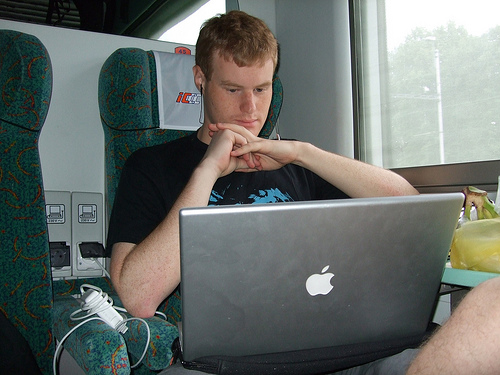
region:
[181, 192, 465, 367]
apple laptop cover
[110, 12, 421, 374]
man sitting down in seat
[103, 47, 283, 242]
velvet green seat on train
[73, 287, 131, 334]
white controller for seat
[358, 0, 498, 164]
thick window on train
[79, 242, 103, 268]
electric outlet with black cover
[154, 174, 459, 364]
the laptop is silver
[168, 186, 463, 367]
the laptop is silver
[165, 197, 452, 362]
the laptop is silver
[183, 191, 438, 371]
the laptop is silver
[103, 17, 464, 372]
the man with laptop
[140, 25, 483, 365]
the man with laptop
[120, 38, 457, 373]
the man with laptop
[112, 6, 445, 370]
the man with laptop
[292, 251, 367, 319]
this is an apple logo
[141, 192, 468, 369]
this is a laptop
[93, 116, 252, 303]
the hand of a person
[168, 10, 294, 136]
the head of a person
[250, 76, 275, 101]
the eye of a person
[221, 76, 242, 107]
the eye of a person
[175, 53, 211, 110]
the ear of a person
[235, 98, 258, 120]
the nose of a person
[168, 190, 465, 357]
silver laptop with white apple logo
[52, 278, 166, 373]
gray cord wrapped around charger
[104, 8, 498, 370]
man with a laptop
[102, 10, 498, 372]
man wearing a black shirt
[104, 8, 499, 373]
man sitting on a seat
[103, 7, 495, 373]
man with hairy leg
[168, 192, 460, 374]
laptop on a laptop case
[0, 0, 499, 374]
inside of a bus with green seats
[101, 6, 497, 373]
man with earbuds in his ears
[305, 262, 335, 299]
apple sign on back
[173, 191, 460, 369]
the grey laptop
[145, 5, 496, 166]
windows on the right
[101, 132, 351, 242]
a black and blue shirt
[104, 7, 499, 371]
a man sitting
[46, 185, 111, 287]
a port in middle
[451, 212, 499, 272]
yellow container on counter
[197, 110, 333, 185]
hands are crossed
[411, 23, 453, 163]
a pole on side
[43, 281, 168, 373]
Charing cord for laptop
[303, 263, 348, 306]
Apple logo for Mac laptop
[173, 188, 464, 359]
Laptop on man's lap